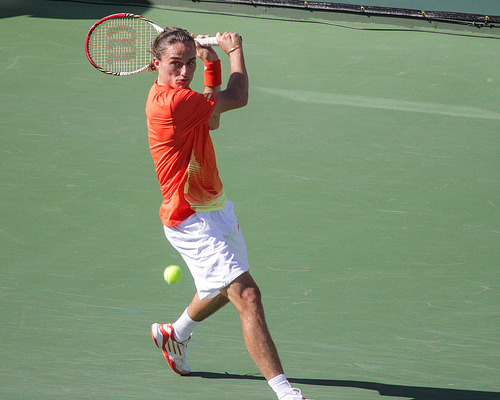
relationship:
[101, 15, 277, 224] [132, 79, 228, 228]
man wearing a shirt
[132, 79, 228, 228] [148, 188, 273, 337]
shirt and shorts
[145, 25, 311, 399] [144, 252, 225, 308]
female hitting ball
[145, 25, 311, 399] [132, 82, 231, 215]
female wearing shirt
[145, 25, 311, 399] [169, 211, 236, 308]
female wearing shorts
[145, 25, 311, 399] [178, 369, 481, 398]
female casting shadow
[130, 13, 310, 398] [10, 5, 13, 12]
female in court